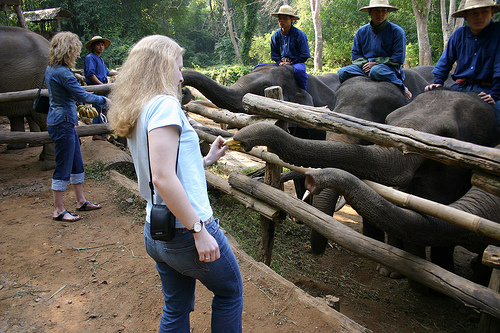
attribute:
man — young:
[424, 0, 497, 105]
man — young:
[337, 1, 412, 96]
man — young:
[251, 3, 309, 88]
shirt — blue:
[281, 44, 293, 54]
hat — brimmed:
[284, 37, 291, 46]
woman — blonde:
[105, 34, 245, 331]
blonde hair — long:
[103, 31, 198, 138]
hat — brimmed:
[452, 4, 496, 21]